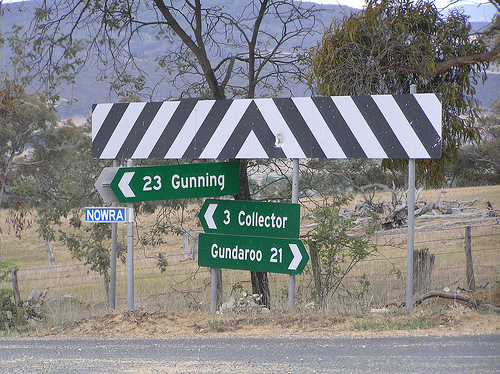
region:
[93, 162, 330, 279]
three green and white signs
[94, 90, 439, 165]
a black and white sign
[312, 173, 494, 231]
a pile of dead tree branches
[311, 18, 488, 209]
a tree with lots of leaves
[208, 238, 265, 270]
Gundaroo on the sign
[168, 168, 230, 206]
Gunning on the sign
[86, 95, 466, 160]
white sign with black lines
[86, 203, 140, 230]
a blue and white sign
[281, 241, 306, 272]
an arrow pointing to the left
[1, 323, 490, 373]
a road in front of signs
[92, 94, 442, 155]
black and white barrier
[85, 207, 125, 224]
blue and white sign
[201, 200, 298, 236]
green and white sign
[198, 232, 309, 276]
street sign on post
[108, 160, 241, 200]
city sign on post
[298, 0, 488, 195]
tree with green leaves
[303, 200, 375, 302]
bush with green leaves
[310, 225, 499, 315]
wire and wood fence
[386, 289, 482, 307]
tree branch on ground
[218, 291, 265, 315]
grey rocks on ground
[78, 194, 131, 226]
a blue and white sign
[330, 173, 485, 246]
a pile of dead branches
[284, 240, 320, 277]
white arrow pointing to the right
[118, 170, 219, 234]
two white arrows pointing to the left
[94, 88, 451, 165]
a white sign with black stripes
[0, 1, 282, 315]
a tree behind the signs with barely any leaves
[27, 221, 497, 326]
a fence behind the signs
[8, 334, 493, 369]
a gravel road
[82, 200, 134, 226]
a small blue sign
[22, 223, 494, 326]
a fence behind the sign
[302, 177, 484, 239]
a pile of sticks behind the fence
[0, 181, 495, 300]
a field behind the fence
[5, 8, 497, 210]
trees behind the field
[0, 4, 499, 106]
a hill behind the trees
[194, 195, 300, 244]
this sign is pointing left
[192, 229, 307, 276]
this sign is pointing right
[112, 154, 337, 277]
Three signs are green.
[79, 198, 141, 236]
One sign is blue.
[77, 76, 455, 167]
The sign is black and white.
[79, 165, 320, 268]
The four smaller signs are in front of the big sign.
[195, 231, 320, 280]
The sign is pointing to the right.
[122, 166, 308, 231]
The signs are pointing to the left.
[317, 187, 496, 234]
The tree branch is behind the signs.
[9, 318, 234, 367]
The road has gravel on it.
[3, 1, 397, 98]
The mountain is in the background.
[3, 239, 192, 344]
The fence is behind the signs.